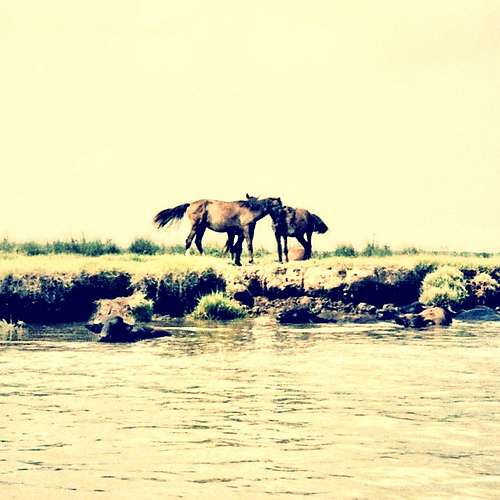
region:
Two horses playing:
[182, 187, 328, 247]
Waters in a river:
[125, 380, 380, 463]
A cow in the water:
[85, 304, 175, 359]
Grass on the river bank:
[197, 286, 255, 323]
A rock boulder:
[227, 269, 267, 311]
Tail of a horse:
[137, 193, 190, 222]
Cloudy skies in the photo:
[117, 64, 239, 154]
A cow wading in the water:
[92, 304, 184, 354]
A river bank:
[37, 269, 284, 313]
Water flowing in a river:
[205, 360, 405, 430]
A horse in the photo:
[169, 179, 268, 244]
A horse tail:
[145, 194, 193, 233]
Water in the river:
[200, 401, 343, 473]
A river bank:
[204, 274, 376, 324]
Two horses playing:
[169, 185, 336, 254]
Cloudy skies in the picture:
[104, 132, 189, 184]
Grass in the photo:
[65, 234, 127, 256]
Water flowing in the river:
[228, 338, 376, 435]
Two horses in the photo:
[178, 180, 330, 269]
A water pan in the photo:
[225, 361, 377, 444]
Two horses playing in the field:
[177, 180, 319, 252]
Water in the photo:
[197, 372, 364, 444]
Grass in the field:
[59, 239, 134, 266]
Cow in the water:
[80, 302, 162, 353]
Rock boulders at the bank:
[227, 278, 294, 300]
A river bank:
[57, 285, 345, 327]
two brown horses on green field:
[145, 189, 335, 264]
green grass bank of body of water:
[3, 250, 497, 337]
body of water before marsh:
[2, 317, 499, 499]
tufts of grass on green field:
[2, 230, 158, 258]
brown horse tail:
[147, 195, 188, 232]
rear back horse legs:
[179, 225, 211, 261]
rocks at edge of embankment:
[253, 290, 398, 329]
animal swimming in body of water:
[91, 310, 171, 355]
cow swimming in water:
[269, 300, 339, 337]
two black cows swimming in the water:
[86, 297, 339, 357]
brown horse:
[137, 189, 274, 264]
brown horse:
[256, 189, 316, 269]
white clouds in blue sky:
[20, 22, 88, 89]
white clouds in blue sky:
[17, 53, 88, 141]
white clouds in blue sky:
[103, 21, 224, 98]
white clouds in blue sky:
[223, 9, 281, 56]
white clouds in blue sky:
[302, 32, 404, 124]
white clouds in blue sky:
[356, 86, 483, 186]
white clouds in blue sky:
[46, 108, 111, 168]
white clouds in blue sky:
[107, 49, 238, 151]